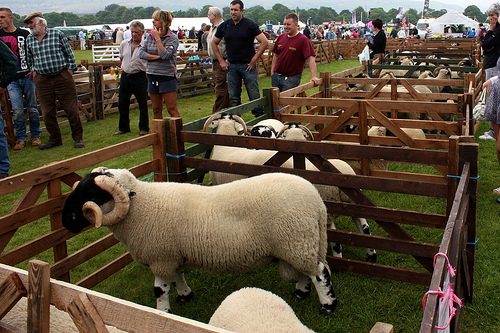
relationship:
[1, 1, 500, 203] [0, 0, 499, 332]
people at fair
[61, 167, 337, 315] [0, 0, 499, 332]
ram at fair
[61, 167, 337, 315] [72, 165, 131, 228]
ram has horns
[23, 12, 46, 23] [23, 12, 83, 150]
hat on man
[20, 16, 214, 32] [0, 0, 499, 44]
tent in background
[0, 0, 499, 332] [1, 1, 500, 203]
fair filled with people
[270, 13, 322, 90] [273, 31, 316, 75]
man in shirt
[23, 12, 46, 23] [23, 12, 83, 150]
cap on man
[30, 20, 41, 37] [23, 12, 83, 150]
beard on man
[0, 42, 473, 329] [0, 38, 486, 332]
sheep in enclosures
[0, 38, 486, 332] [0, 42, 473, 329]
enclosures around sheep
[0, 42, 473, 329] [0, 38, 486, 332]
sheep in different enclosures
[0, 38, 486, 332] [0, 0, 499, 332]
enclosures at fair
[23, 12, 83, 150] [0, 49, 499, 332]
man standing on grass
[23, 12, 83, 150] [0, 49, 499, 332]
man on grass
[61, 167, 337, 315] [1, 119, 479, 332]
ram in enclosure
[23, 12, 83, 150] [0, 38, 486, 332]
man leaning on enclosures